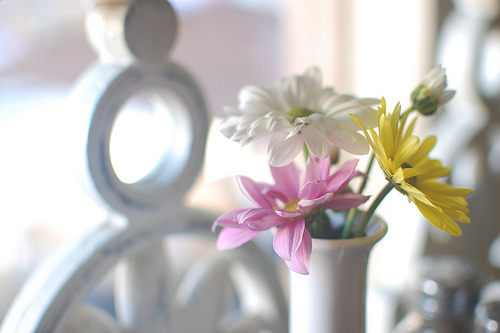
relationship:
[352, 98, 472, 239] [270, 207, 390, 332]
flower in vase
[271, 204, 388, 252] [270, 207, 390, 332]
rim of vase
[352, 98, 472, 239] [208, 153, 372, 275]
flower and daisy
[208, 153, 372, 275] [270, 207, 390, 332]
daisy in vase